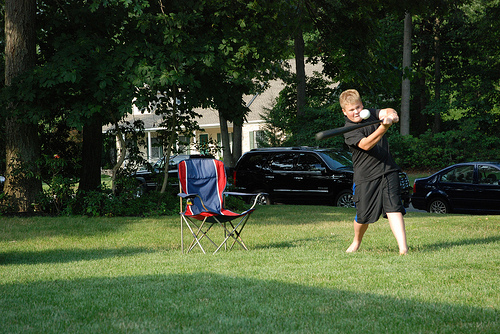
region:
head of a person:
[332, 82, 374, 127]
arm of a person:
[357, 122, 400, 152]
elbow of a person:
[349, 136, 383, 158]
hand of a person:
[376, 105, 407, 127]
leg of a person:
[340, 190, 380, 240]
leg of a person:
[375, 185, 410, 245]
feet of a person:
[345, 242, 370, 255]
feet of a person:
[397, 241, 427, 267]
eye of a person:
[345, 100, 363, 114]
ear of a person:
[337, 105, 347, 119]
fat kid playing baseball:
[294, 90, 454, 257]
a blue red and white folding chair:
[158, 158, 267, 248]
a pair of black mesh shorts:
[332, 171, 426, 243]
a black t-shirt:
[339, 114, 414, 176]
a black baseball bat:
[294, 113, 406, 136]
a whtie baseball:
[347, 103, 381, 133]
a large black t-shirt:
[322, 113, 423, 182]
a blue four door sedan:
[409, 150, 499, 220]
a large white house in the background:
[100, 40, 387, 178]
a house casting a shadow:
[0, 260, 496, 332]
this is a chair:
[158, 133, 278, 259]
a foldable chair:
[155, 117, 280, 291]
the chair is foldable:
[168, 128, 266, 273]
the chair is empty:
[153, 123, 262, 265]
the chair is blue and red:
[152, 128, 312, 286]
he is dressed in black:
[306, 53, 452, 265]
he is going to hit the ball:
[283, 64, 465, 294]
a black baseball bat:
[282, 112, 456, 144]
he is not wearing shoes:
[307, 208, 470, 282]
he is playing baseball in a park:
[292, 65, 457, 271]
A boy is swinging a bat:
[307, 84, 417, 263]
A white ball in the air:
[357, 105, 377, 121]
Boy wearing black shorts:
[348, 168, 408, 225]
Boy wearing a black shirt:
[338, 113, 401, 179]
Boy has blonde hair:
[331, 82, 371, 123]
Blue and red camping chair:
[170, 153, 267, 248]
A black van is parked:
[234, 144, 409, 212]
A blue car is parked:
[411, 159, 499, 216]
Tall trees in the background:
[40, 57, 171, 237]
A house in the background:
[101, 52, 349, 160]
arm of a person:
[353, 125, 381, 149]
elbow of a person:
[351, 139, 371, 152]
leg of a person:
[340, 187, 385, 242]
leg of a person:
[380, 182, 425, 242]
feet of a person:
[392, 241, 433, 256]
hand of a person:
[380, 100, 398, 127]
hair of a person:
[340, 91, 350, 105]